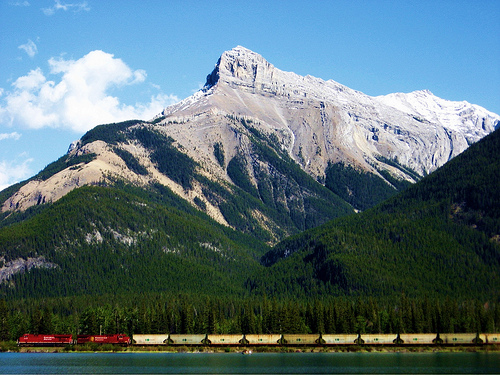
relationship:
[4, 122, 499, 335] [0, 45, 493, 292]
trees covering mountain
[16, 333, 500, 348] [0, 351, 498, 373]
bus by water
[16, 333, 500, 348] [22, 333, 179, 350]
bus has cars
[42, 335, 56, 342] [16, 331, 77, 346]
white writing on train car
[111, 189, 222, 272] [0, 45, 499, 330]
trees on mountain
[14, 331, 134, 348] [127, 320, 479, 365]
red train in bus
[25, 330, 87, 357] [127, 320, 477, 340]
red train in bus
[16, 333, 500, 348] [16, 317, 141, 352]
bus in bus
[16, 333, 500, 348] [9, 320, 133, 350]
bus in bus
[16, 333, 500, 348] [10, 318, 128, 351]
bus in bus